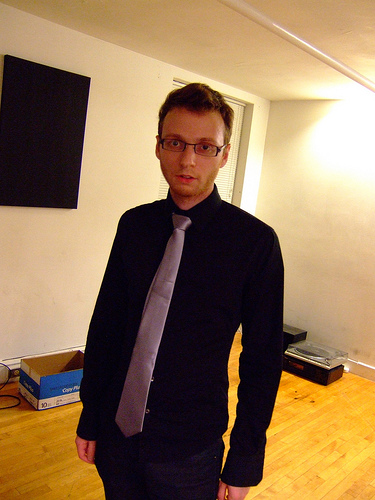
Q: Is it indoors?
A: Yes, it is indoors.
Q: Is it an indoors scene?
A: Yes, it is indoors.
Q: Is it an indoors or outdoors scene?
A: It is indoors.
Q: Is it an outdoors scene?
A: No, it is indoors.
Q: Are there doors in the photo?
A: Yes, there is a door.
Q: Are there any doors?
A: Yes, there is a door.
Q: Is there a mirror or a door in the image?
A: Yes, there is a door.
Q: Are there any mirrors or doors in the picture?
A: Yes, there is a door.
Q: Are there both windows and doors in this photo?
A: Yes, there are both a door and a window.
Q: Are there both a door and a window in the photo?
A: Yes, there are both a door and a window.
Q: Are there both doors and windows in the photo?
A: Yes, there are both a door and a window.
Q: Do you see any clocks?
A: No, there are no clocks.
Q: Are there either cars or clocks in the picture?
A: No, there are no clocks or cars.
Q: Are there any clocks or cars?
A: No, there are no clocks or cars.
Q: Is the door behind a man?
A: Yes, the door is behind a man.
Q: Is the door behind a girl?
A: No, the door is behind a man.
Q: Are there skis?
A: No, there are no skis.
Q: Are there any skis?
A: No, there are no skis.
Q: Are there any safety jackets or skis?
A: No, there are no skis or safety jackets.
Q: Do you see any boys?
A: No, there are no boys.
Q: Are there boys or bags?
A: No, there are no boys or bags.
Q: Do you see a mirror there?
A: No, there are no mirrors.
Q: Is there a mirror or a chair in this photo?
A: No, there are no mirrors or chairs.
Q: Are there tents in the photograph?
A: No, there are no tents.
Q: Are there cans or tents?
A: No, there are no tents or cans.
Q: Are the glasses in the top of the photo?
A: Yes, the glasses are in the top of the image.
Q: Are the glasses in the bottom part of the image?
A: No, the glasses are in the top of the image.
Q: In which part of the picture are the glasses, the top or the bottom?
A: The glasses are in the top of the image.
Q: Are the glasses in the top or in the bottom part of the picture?
A: The glasses are in the top of the image.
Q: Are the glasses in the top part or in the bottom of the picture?
A: The glasses are in the top of the image.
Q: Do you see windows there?
A: Yes, there is a window.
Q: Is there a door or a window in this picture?
A: Yes, there is a window.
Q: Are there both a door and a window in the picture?
A: Yes, there are both a window and a door.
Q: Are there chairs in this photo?
A: No, there are no chairs.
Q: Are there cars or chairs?
A: No, there are no chairs or cars.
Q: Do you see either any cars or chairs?
A: No, there are no chairs or cars.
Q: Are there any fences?
A: No, there are no fences.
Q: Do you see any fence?
A: No, there are no fences.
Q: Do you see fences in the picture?
A: No, there are no fences.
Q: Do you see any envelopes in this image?
A: No, there are no envelopes.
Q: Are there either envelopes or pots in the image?
A: No, there are no envelopes or pots.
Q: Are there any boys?
A: No, there are no boys.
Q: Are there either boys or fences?
A: No, there are no boys or fences.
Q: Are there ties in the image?
A: Yes, there is a tie.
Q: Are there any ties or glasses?
A: Yes, there is a tie.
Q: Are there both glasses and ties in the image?
A: Yes, there are both a tie and glasses.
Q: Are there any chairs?
A: No, there are no chairs.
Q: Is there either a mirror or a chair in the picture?
A: No, there are no chairs or mirrors.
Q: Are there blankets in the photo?
A: No, there are no blankets.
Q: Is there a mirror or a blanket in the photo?
A: No, there are no blankets or mirrors.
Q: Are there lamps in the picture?
A: No, there are no lamps.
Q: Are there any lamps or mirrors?
A: No, there are no lamps or mirrors.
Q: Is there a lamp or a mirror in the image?
A: No, there are no lamps or mirrors.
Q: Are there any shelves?
A: No, there are no shelves.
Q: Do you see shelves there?
A: No, there are no shelves.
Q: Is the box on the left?
A: Yes, the box is on the left of the image.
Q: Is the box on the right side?
A: No, the box is on the left of the image.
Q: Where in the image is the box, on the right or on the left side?
A: The box is on the left of the image.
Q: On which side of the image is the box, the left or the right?
A: The box is on the left of the image.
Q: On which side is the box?
A: The box is on the left of the image.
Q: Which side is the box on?
A: The box is on the left of the image.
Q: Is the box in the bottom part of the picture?
A: Yes, the box is in the bottom of the image.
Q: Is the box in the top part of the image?
A: No, the box is in the bottom of the image.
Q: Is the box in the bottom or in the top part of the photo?
A: The box is in the bottom of the image.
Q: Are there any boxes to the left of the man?
A: Yes, there is a box to the left of the man.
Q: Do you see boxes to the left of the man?
A: Yes, there is a box to the left of the man.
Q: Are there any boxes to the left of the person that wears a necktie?
A: Yes, there is a box to the left of the man.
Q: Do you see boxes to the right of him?
A: No, the box is to the left of the man.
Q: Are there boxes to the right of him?
A: No, the box is to the left of the man.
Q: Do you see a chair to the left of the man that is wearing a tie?
A: No, there is a box to the left of the man.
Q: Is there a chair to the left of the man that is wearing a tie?
A: No, there is a box to the left of the man.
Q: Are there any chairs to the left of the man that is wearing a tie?
A: No, there is a box to the left of the man.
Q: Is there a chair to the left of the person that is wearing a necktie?
A: No, there is a box to the left of the man.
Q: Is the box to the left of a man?
A: Yes, the box is to the left of a man.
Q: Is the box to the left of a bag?
A: No, the box is to the left of a man.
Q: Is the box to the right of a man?
A: No, the box is to the left of a man.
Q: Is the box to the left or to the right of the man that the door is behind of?
A: The box is to the left of the man.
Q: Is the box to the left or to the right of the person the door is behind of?
A: The box is to the left of the man.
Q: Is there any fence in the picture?
A: No, there are no fences.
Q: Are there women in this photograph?
A: No, there are no women.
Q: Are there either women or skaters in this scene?
A: No, there are no women or skaters.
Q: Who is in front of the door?
A: The man is in front of the door.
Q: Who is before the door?
A: The man is in front of the door.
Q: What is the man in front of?
A: The man is in front of the door.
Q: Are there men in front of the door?
A: Yes, there is a man in front of the door.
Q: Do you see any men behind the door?
A: No, the man is in front of the door.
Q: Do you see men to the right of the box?
A: Yes, there is a man to the right of the box.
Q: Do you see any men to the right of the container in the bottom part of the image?
A: Yes, there is a man to the right of the box.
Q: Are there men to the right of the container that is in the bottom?
A: Yes, there is a man to the right of the box.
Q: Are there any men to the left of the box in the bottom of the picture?
A: No, the man is to the right of the box.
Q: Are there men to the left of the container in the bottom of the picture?
A: No, the man is to the right of the box.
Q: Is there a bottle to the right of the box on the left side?
A: No, there is a man to the right of the box.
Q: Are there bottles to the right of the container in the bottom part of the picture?
A: No, there is a man to the right of the box.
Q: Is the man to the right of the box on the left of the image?
A: Yes, the man is to the right of the box.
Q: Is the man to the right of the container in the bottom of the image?
A: Yes, the man is to the right of the box.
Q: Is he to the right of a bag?
A: No, the man is to the right of the box.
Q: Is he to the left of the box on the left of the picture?
A: No, the man is to the right of the box.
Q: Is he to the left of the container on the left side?
A: No, the man is to the right of the box.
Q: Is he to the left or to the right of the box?
A: The man is to the right of the box.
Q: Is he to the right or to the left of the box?
A: The man is to the right of the box.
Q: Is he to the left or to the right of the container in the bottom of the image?
A: The man is to the right of the box.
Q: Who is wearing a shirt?
A: The man is wearing a shirt.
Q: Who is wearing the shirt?
A: The man is wearing a shirt.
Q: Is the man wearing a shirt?
A: Yes, the man is wearing a shirt.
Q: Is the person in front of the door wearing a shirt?
A: Yes, the man is wearing a shirt.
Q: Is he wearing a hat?
A: No, the man is wearing a shirt.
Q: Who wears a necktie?
A: The man wears a necktie.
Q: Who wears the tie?
A: The man wears a necktie.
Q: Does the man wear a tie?
A: Yes, the man wears a tie.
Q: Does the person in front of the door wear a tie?
A: Yes, the man wears a tie.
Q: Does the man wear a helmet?
A: No, the man wears a tie.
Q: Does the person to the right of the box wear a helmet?
A: No, the man wears a tie.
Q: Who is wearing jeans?
A: The man is wearing jeans.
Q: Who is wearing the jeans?
A: The man is wearing jeans.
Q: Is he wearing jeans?
A: Yes, the man is wearing jeans.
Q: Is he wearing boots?
A: No, the man is wearing jeans.